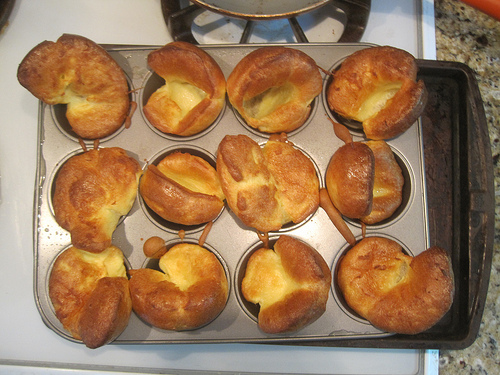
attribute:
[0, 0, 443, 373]
oven — white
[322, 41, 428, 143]
bread — brown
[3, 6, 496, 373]
counter — granite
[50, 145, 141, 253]
bread — brown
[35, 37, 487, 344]
top — white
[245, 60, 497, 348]
pan — black, metal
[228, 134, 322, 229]
bread — brown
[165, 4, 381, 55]
burner — black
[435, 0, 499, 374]
granite countertop — black, grey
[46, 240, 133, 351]
bread — brown 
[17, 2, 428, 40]
stove — white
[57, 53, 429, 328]
popovers — brown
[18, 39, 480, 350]
bread — brown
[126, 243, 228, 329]
bread — brown 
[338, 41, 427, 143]
bread — brown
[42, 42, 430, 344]
tin — non-stick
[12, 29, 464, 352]
popovers — golden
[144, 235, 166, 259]
crumb — large, brown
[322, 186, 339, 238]
crumb — large, brown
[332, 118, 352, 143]
crumb — large, brown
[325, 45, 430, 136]
croissants — brown 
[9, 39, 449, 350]
pan — silver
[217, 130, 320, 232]
bread — brown